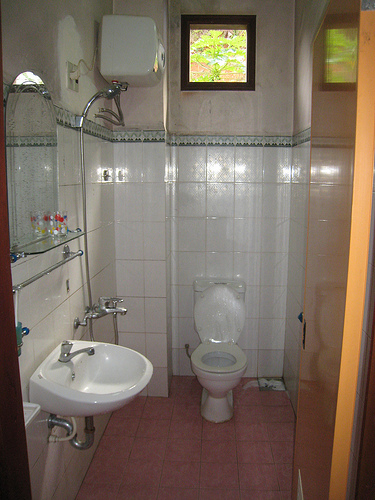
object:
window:
[179, 15, 257, 88]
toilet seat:
[190, 343, 249, 376]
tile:
[234, 440, 276, 468]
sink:
[29, 336, 154, 420]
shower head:
[80, 85, 118, 123]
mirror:
[6, 72, 62, 256]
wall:
[3, 2, 337, 499]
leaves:
[190, 35, 214, 51]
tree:
[190, 31, 246, 80]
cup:
[50, 211, 68, 238]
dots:
[54, 214, 61, 222]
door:
[298, 2, 373, 498]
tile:
[141, 182, 166, 223]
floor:
[74, 373, 298, 499]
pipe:
[48, 412, 97, 453]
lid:
[194, 287, 245, 342]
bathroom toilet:
[191, 279, 247, 423]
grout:
[235, 441, 241, 468]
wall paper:
[57, 106, 165, 142]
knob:
[59, 338, 72, 354]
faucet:
[58, 340, 95, 363]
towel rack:
[10, 245, 85, 297]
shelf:
[19, 224, 84, 256]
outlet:
[66, 60, 80, 94]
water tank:
[194, 279, 247, 333]